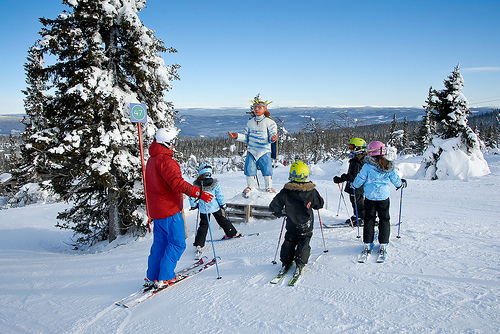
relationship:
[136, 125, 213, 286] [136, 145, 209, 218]
skier wearing jacket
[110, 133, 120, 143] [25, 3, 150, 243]
snow on tree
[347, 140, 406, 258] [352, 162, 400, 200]
child wearing blue sweater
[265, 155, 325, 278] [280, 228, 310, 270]
child wearing black pants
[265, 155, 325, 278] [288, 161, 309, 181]
child wearing helmet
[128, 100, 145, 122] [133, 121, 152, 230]
sign on red pole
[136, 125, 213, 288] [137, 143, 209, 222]
skier wearing coat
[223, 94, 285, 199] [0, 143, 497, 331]
statue on mound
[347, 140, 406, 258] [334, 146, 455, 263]
child wearing jacket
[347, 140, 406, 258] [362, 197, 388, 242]
child in pants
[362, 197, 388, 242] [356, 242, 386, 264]
pants on skis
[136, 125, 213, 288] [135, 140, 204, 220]
skier in jacket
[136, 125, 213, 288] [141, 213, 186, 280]
skier in pants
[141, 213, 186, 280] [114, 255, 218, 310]
pants on skis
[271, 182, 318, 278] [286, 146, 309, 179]
child in helmet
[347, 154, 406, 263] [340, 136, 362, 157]
child in helmet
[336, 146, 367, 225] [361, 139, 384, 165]
child in helmet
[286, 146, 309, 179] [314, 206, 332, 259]
helmet on ski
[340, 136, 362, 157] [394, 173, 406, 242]
helmet on ski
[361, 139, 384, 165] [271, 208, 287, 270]
helmet on ski